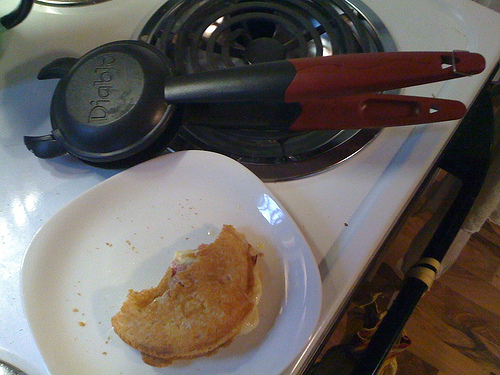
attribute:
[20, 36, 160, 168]
circular panel — flat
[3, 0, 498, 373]
stove — white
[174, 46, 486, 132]
handle — long, red, black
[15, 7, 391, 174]
cooker — made, steel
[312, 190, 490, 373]
floor — wooden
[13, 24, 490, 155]
utensil — diablo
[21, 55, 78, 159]
curved hinges — pointy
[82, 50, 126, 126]
word — black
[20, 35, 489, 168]
cooker — black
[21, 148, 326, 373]
plate — square, white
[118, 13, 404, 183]
stove — white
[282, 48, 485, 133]
handles — red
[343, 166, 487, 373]
floor — wooden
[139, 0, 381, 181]
coil — electric, black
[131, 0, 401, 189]
electric coil — black